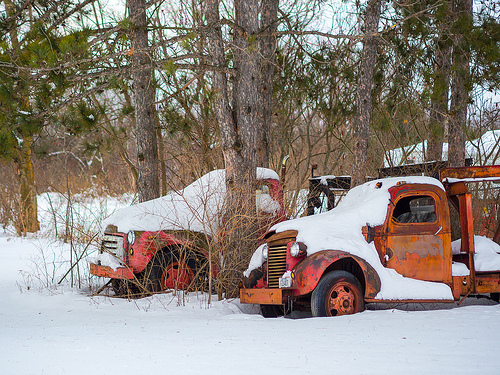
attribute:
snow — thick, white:
[7, 240, 105, 368]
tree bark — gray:
[229, 54, 261, 266]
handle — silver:
[434, 224, 444, 239]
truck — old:
[239, 153, 493, 340]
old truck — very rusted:
[267, 148, 451, 320]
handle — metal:
[430, 223, 445, 237]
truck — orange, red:
[241, 168, 498, 313]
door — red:
[388, 190, 448, 289]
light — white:
[288, 239, 308, 260]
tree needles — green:
[2, 32, 103, 159]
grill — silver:
[94, 229, 126, 273]